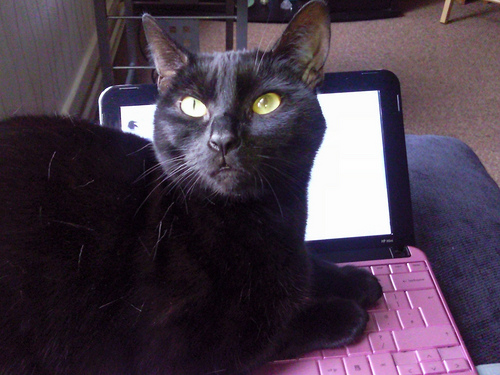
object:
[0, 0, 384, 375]
cat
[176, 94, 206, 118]
eyes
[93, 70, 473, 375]
computer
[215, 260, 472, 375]
keyboard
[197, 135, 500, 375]
chair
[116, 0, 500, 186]
floor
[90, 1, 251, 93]
metal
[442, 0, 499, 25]
wood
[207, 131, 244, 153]
nose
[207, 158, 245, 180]
mouth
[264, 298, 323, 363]
legs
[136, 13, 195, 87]
ears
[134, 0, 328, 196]
head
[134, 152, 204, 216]
whiskers